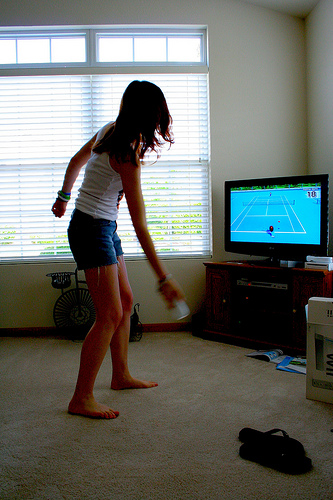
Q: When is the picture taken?
A: Daytime.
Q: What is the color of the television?
A: Black.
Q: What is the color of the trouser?
A: Blue.